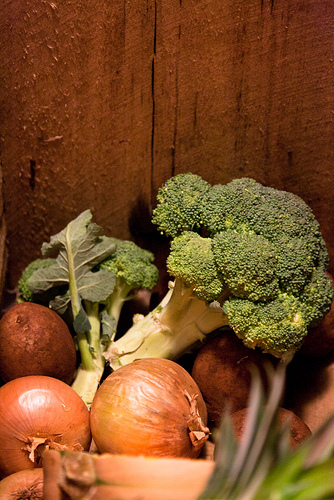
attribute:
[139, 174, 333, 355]
broccoli — green, plant, large, bushy, floret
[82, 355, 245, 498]
onion — large, round, brown, orange, small, crinkly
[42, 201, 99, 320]
leaf — green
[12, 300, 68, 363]
potato — brown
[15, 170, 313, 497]
vegetables — stacked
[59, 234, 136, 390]
vegetable — green, leafy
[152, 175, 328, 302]
head — large, green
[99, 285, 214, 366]
stem — green, vegetable, thick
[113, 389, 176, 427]
skin — shiny, brown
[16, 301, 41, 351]
skin — brown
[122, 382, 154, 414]
reflection — light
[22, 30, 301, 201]
plant — wooden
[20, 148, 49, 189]
oval — brown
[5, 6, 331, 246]
plank — wooden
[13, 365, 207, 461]
onions — next to each other, brown, side by side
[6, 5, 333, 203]
wall — rough, brown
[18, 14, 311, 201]
crate — brown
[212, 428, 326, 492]
leaves — green